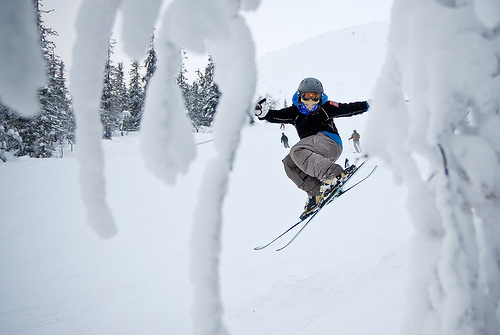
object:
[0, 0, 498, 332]
mountain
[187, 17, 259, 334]
tree branch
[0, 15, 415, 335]
ground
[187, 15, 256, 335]
leaf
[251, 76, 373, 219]
skier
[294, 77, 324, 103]
helmet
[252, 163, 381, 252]
ski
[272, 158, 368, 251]
ski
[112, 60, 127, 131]
tree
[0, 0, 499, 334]
snow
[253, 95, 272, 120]
glove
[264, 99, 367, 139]
jacket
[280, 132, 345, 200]
pants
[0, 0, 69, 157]
trees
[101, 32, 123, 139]
branch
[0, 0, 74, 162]
branch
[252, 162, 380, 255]
pair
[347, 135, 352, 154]
pole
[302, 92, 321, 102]
goggles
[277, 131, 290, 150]
skier